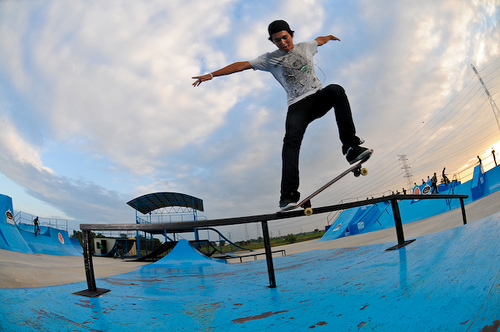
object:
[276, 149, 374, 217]
skateboard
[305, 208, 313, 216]
wheels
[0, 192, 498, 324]
skatepark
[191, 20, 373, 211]
boy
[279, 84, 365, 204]
jeans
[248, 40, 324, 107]
white shirt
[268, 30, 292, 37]
dark hair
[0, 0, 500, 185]
sky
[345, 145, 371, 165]
sneakers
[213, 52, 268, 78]
arms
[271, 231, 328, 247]
grass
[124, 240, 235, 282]
ramp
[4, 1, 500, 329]
picture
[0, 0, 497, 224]
clouds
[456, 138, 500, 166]
sun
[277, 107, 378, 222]
tricks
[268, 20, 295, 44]
hat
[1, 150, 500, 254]
railing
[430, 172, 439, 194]
people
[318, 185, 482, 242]
ramp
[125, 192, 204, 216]
canopy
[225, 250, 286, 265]
bench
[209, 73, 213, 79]
bracelet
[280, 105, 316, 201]
leg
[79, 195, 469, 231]
rail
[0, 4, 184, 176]
background